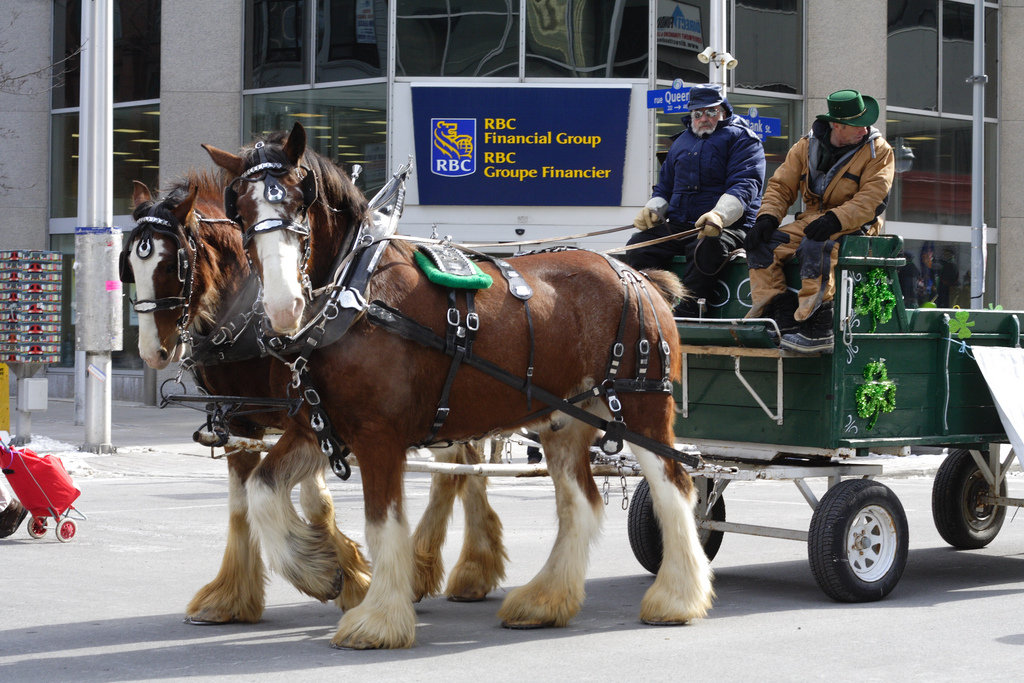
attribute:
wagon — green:
[645, 201, 944, 506]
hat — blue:
[675, 87, 732, 120]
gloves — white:
[627, 193, 748, 233]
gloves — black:
[753, 210, 836, 254]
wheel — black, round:
[809, 485, 918, 598]